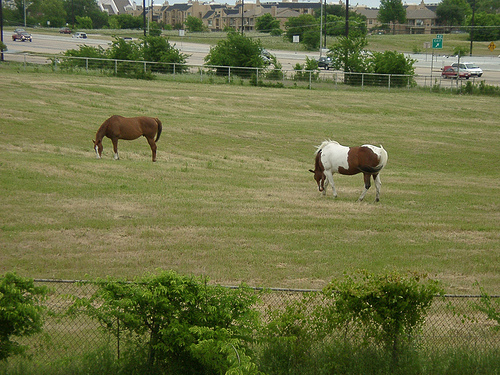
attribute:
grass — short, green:
[2, 64, 496, 302]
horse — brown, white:
[299, 132, 406, 214]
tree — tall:
[63, 38, 105, 68]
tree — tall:
[104, 40, 147, 80]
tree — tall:
[143, 28, 180, 73]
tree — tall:
[204, 31, 272, 86]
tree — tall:
[334, 22, 369, 82]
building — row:
[401, 3, 438, 35]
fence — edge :
[269, 275, 284, 297]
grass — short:
[0, 59, 490, 356]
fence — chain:
[4, 273, 494, 372]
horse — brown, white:
[90, 109, 162, 165]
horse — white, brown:
[306, 140, 389, 210]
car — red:
[256, 48, 273, 63]